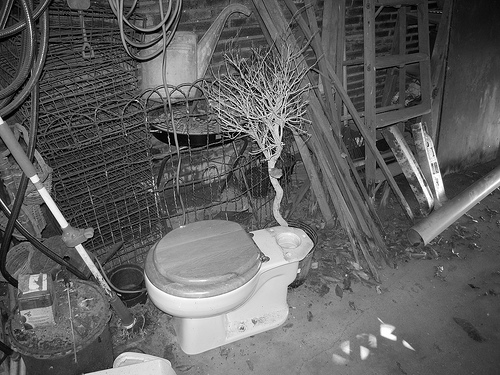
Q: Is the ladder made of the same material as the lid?
A: Yes, both the ladder and the lid are made of wood.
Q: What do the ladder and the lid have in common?
A: The material, both the ladder and the lid are wooden.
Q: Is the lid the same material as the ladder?
A: Yes, both the lid and the ladder are made of wood.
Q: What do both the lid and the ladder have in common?
A: The material, both the lid and the ladder are wooden.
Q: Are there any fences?
A: Yes, there is a fence.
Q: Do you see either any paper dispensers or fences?
A: Yes, there is a fence.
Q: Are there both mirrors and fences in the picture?
A: No, there is a fence but no mirrors.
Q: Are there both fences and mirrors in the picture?
A: No, there is a fence but no mirrors.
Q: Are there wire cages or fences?
A: Yes, there is a wire fence.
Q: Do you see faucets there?
A: No, there are no faucets.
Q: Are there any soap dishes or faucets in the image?
A: No, there are no faucets or soap dishes.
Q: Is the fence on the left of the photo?
A: Yes, the fence is on the left of the image.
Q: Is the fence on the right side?
A: No, the fence is on the left of the image.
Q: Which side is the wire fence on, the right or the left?
A: The fence is on the left of the image.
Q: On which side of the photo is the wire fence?
A: The fence is on the left of the image.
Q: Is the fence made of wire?
A: Yes, the fence is made of wire.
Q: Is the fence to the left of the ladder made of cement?
A: No, the fence is made of wire.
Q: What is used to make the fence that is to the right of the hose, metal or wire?
A: The fence is made of wire.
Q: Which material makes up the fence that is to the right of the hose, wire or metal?
A: The fence is made of wire.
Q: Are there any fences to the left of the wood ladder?
A: Yes, there is a fence to the left of the ladder.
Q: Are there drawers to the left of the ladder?
A: No, there is a fence to the left of the ladder.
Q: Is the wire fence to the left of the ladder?
A: Yes, the fence is to the left of the ladder.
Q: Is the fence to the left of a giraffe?
A: No, the fence is to the left of the ladder.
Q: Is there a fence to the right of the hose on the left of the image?
A: Yes, there is a fence to the right of the hose.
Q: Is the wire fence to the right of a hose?
A: Yes, the fence is to the right of a hose.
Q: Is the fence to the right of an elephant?
A: No, the fence is to the right of a hose.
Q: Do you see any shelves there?
A: No, there are no shelves.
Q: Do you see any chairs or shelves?
A: No, there are no shelves or chairs.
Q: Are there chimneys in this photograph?
A: No, there are no chimneys.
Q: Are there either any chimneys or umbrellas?
A: No, there are no chimneys or umbrellas.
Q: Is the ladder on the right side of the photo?
A: Yes, the ladder is on the right of the image.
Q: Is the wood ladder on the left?
A: No, the ladder is on the right of the image.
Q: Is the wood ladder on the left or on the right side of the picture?
A: The ladder is on the right of the image.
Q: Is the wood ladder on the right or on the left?
A: The ladder is on the right of the image.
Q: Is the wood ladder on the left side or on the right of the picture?
A: The ladder is on the right of the image.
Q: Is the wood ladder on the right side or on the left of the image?
A: The ladder is on the right of the image.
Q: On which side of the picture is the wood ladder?
A: The ladder is on the right of the image.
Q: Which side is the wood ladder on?
A: The ladder is on the right of the image.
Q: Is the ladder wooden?
A: Yes, the ladder is wooden.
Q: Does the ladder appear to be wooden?
A: Yes, the ladder is wooden.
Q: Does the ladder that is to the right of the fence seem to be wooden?
A: Yes, the ladder is wooden.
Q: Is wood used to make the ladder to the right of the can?
A: Yes, the ladder is made of wood.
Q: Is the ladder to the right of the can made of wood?
A: Yes, the ladder is made of wood.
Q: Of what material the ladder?
A: The ladder is made of wood.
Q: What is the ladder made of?
A: The ladder is made of wood.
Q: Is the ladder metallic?
A: No, the ladder is wooden.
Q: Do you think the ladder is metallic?
A: No, the ladder is wooden.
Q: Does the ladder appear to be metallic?
A: No, the ladder is wooden.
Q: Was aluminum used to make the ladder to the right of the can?
A: No, the ladder is made of wood.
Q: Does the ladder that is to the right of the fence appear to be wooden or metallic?
A: The ladder is wooden.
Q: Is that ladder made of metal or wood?
A: The ladder is made of wood.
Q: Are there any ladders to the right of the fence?
A: Yes, there is a ladder to the right of the fence.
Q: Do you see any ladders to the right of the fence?
A: Yes, there is a ladder to the right of the fence.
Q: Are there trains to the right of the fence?
A: No, there is a ladder to the right of the fence.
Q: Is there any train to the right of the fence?
A: No, there is a ladder to the right of the fence.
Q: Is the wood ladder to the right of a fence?
A: Yes, the ladder is to the right of a fence.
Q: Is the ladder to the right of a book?
A: No, the ladder is to the right of a fence.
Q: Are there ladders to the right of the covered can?
A: Yes, there is a ladder to the right of the can.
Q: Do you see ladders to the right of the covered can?
A: Yes, there is a ladder to the right of the can.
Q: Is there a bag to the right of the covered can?
A: No, there is a ladder to the right of the can.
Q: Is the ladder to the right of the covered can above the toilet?
A: Yes, the ladder is to the right of the can.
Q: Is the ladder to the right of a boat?
A: No, the ladder is to the right of the can.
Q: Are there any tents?
A: No, there are no tents.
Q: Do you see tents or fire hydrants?
A: No, there are no tents or fire hydrants.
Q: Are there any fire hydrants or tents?
A: No, there are no tents or fire hydrants.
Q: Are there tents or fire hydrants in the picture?
A: No, there are no tents or fire hydrants.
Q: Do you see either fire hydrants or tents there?
A: No, there are no tents or fire hydrants.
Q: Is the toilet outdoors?
A: Yes, the toilet is outdoors.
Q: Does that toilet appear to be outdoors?
A: Yes, the toilet is outdoors.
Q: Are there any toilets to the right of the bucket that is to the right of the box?
A: Yes, there is a toilet to the right of the bucket.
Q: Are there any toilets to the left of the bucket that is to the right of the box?
A: No, the toilet is to the right of the bucket.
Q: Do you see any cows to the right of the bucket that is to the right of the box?
A: No, there is a toilet to the right of the bucket.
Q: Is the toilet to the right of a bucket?
A: Yes, the toilet is to the right of a bucket.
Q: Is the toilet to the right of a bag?
A: No, the toilet is to the right of a bucket.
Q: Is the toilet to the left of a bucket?
A: No, the toilet is to the right of a bucket.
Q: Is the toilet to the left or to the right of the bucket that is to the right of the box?
A: The toilet is to the right of the bucket.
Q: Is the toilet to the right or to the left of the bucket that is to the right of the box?
A: The toilet is to the right of the bucket.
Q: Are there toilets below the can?
A: Yes, there is a toilet below the can.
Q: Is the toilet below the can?
A: Yes, the toilet is below the can.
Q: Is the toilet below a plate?
A: No, the toilet is below the can.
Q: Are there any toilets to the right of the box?
A: Yes, there is a toilet to the right of the box.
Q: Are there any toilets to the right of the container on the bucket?
A: Yes, there is a toilet to the right of the box.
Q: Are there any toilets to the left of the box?
A: No, the toilet is to the right of the box.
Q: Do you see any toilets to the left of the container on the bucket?
A: No, the toilet is to the right of the box.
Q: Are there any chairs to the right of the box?
A: No, there is a toilet to the right of the box.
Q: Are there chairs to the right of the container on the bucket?
A: No, there is a toilet to the right of the box.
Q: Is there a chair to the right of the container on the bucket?
A: No, there is a toilet to the right of the box.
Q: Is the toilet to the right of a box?
A: Yes, the toilet is to the right of a box.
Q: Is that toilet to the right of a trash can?
A: No, the toilet is to the right of a box.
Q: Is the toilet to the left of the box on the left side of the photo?
A: No, the toilet is to the right of the box.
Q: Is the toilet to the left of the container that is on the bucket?
A: No, the toilet is to the right of the box.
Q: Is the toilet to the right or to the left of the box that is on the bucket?
A: The toilet is to the right of the box.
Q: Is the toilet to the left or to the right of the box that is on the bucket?
A: The toilet is to the right of the box.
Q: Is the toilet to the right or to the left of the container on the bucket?
A: The toilet is to the right of the box.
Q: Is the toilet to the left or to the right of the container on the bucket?
A: The toilet is to the right of the box.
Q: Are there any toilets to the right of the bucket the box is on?
A: Yes, there is a toilet to the right of the bucket.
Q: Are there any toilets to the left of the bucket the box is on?
A: No, the toilet is to the right of the bucket.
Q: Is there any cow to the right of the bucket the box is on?
A: No, there is a toilet to the right of the bucket.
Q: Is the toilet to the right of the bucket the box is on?
A: Yes, the toilet is to the right of the bucket.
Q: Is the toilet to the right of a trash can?
A: No, the toilet is to the right of the bucket.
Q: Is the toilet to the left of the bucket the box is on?
A: No, the toilet is to the right of the bucket.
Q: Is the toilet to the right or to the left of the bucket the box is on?
A: The toilet is to the right of the bucket.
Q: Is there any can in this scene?
A: Yes, there is a can.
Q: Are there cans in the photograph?
A: Yes, there is a can.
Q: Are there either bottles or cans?
A: Yes, there is a can.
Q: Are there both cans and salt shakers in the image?
A: No, there is a can but no salt shakers.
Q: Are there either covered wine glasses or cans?
A: Yes, there is a covered can.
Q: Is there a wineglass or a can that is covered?
A: Yes, the can is covered.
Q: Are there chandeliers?
A: No, there are no chandeliers.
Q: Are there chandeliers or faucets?
A: No, there are no chandeliers or faucets.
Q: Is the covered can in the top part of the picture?
A: Yes, the can is in the top of the image.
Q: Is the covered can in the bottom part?
A: No, the can is in the top of the image.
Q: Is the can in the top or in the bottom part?
A: The can is in the top of the image.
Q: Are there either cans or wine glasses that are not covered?
A: No, there is a can but it is covered.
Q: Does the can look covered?
A: Yes, the can is covered.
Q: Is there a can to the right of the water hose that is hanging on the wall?
A: Yes, there is a can to the right of the water hose.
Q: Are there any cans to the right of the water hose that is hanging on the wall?
A: Yes, there is a can to the right of the water hose.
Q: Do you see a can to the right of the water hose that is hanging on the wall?
A: Yes, there is a can to the right of the water hose.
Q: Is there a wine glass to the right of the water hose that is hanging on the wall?
A: No, there is a can to the right of the water hose.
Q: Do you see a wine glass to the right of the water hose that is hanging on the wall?
A: No, there is a can to the right of the water hose.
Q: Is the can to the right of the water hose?
A: Yes, the can is to the right of the water hose.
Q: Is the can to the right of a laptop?
A: No, the can is to the right of the water hose.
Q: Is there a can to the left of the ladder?
A: Yes, there is a can to the left of the ladder.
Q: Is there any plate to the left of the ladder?
A: No, there is a can to the left of the ladder.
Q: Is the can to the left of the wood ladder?
A: Yes, the can is to the left of the ladder.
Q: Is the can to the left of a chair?
A: No, the can is to the left of the ladder.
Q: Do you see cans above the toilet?
A: Yes, there is a can above the toilet.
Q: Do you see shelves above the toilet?
A: No, there is a can above the toilet.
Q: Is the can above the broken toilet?
A: Yes, the can is above the toilet.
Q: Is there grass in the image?
A: Yes, there is grass.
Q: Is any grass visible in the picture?
A: Yes, there is grass.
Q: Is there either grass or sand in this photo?
A: Yes, there is grass.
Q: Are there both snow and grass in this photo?
A: No, there is grass but no snow.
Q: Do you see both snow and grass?
A: No, there is grass but no snow.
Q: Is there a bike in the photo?
A: No, there are no bikes.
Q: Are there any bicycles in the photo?
A: No, there are no bicycles.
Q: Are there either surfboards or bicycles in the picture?
A: No, there are no bicycles or surfboards.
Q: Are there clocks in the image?
A: No, there are no clocks.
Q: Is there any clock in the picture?
A: No, there are no clocks.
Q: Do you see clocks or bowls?
A: No, there are no clocks or bowls.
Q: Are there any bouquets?
A: No, there are no bouquets.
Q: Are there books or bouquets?
A: No, there are no bouquets or books.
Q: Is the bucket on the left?
A: Yes, the bucket is on the left of the image.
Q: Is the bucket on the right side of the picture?
A: No, the bucket is on the left of the image.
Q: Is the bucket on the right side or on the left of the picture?
A: The bucket is on the left of the image.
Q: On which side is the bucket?
A: The bucket is on the left of the image.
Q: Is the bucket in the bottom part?
A: Yes, the bucket is in the bottom of the image.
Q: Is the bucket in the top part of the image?
A: No, the bucket is in the bottom of the image.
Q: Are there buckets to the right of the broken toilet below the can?
A: No, the bucket is to the left of the toilet.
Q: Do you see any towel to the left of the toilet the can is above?
A: No, there is a bucket to the left of the toilet.